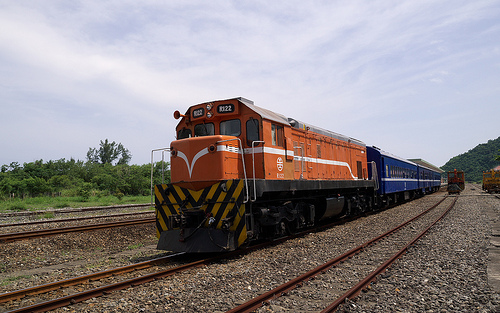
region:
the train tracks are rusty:
[291, 231, 426, 286]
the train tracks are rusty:
[303, 244, 425, 311]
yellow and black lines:
[149, 180, 249, 255]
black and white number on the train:
[218, 103, 233, 114]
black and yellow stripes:
[150, 180, 247, 244]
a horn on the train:
[173, 110, 183, 119]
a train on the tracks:
[150, 96, 442, 253]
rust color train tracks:
[0, 253, 200, 310]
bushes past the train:
[1, 161, 161, 199]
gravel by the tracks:
[337, 193, 492, 310]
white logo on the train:
[275, 155, 282, 170]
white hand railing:
[222, 138, 262, 202]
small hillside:
[446, 140, 496, 180]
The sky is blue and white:
[214, 11, 418, 138]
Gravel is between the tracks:
[337, 217, 442, 302]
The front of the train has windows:
[144, 85, 261, 212]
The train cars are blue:
[361, 115, 458, 241]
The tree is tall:
[77, 122, 134, 202]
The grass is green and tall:
[26, 185, 140, 230]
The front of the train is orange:
[162, 85, 276, 199]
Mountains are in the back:
[446, 140, 498, 180]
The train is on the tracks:
[259, 192, 361, 260]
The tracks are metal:
[26, 193, 150, 310]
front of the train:
[140, 107, 247, 267]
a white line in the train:
[196, 143, 218, 159]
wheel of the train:
[243, 206, 340, 246]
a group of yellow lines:
[202, 183, 243, 220]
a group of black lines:
[195, 185, 242, 222]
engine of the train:
[166, 102, 371, 275]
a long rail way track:
[283, 171, 485, 308]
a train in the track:
[156, 87, 459, 267]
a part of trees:
[26, 145, 159, 199]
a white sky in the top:
[37, 5, 479, 94]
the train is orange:
[165, 90, 372, 199]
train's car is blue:
[368, 139, 455, 211]